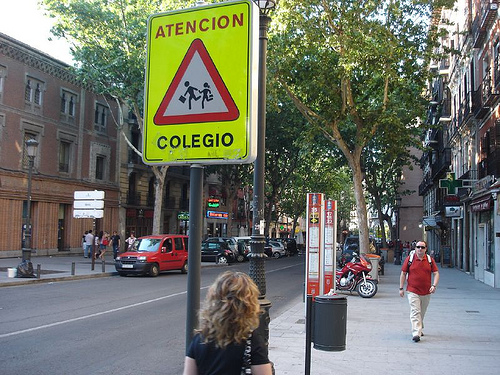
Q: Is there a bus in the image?
A: No, there are no buses.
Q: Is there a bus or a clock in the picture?
A: No, there are no buses or clocks.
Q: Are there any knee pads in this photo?
A: No, there are no knee pads.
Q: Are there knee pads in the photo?
A: No, there are no knee pads.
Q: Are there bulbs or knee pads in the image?
A: No, there are no knee pads or bulbs.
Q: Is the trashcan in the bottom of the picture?
A: Yes, the trashcan is in the bottom of the image.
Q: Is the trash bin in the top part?
A: No, the trash bin is in the bottom of the image.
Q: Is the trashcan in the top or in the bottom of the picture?
A: The trashcan is in the bottom of the image.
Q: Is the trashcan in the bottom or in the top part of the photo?
A: The trashcan is in the bottom of the image.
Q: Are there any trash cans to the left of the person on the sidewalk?
A: Yes, there is a trash can to the left of the person.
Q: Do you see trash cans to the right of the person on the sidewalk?
A: No, the trash can is to the left of the person.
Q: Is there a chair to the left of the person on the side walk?
A: No, there is a trash can to the left of the person.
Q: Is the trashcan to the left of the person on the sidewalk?
A: Yes, the trashcan is to the left of the person.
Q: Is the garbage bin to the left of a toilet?
A: No, the garbage bin is to the left of the person.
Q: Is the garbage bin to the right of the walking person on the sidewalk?
A: No, the garbage bin is to the left of the person.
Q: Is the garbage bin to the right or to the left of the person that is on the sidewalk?
A: The garbage bin is to the left of the person.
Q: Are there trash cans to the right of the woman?
A: Yes, there is a trash can to the right of the woman.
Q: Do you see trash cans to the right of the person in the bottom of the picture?
A: Yes, there is a trash can to the right of the woman.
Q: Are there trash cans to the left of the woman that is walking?
A: No, the trash can is to the right of the woman.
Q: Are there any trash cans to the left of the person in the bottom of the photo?
A: No, the trash can is to the right of the woman.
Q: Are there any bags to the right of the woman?
A: No, there is a trash can to the right of the woman.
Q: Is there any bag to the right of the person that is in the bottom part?
A: No, there is a trash can to the right of the woman.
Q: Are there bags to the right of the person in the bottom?
A: No, there is a trash can to the right of the woman.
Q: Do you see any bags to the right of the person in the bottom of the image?
A: No, there is a trash can to the right of the woman.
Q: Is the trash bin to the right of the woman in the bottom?
A: Yes, the trash bin is to the right of the woman.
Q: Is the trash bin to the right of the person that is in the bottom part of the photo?
A: Yes, the trash bin is to the right of the woman.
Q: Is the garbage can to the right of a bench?
A: No, the garbage can is to the right of the woman.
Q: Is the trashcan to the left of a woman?
A: No, the trashcan is to the right of a woman.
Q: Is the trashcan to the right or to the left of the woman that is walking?
A: The trashcan is to the right of the woman.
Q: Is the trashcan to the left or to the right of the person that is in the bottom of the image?
A: The trashcan is to the right of the woman.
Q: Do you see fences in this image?
A: No, there are no fences.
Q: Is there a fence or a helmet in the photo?
A: No, there are no fences or helmets.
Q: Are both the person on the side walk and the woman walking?
A: Yes, both the person and the woman are walking.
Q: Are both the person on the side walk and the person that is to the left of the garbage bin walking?
A: Yes, both the person and the woman are walking.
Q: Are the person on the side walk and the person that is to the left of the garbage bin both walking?
A: Yes, both the person and the woman are walking.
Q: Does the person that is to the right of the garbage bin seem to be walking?
A: Yes, the person is walking.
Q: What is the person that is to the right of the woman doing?
A: The person is walking.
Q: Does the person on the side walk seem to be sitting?
A: No, the person is walking.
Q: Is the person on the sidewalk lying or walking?
A: The person is walking.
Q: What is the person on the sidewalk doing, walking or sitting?
A: The person is walking.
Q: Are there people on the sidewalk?
A: Yes, there is a person on the sidewalk.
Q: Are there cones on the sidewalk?
A: No, there is a person on the sidewalk.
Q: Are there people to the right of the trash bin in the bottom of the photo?
A: Yes, there is a person to the right of the garbage bin.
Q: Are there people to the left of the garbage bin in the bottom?
A: No, the person is to the right of the garbage bin.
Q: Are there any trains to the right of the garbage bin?
A: No, there is a person to the right of the garbage bin.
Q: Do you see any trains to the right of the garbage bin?
A: No, there is a person to the right of the garbage bin.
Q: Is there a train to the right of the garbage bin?
A: No, there is a person to the right of the garbage bin.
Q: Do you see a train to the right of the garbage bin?
A: No, there is a person to the right of the garbage bin.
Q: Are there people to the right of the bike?
A: Yes, there is a person to the right of the bike.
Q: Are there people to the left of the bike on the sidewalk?
A: No, the person is to the right of the bike.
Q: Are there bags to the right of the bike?
A: No, there is a person to the right of the bike.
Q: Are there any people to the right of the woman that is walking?
A: Yes, there is a person to the right of the woman.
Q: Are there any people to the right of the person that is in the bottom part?
A: Yes, there is a person to the right of the woman.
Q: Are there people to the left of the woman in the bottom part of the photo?
A: No, the person is to the right of the woman.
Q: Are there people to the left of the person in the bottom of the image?
A: No, the person is to the right of the woman.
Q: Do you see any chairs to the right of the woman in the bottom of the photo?
A: No, there is a person to the right of the woman.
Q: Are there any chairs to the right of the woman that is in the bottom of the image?
A: No, there is a person to the right of the woman.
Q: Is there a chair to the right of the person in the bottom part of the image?
A: No, there is a person to the right of the woman.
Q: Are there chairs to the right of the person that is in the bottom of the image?
A: No, there is a person to the right of the woman.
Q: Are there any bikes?
A: Yes, there is a bike.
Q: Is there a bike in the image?
A: Yes, there is a bike.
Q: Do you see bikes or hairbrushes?
A: Yes, there is a bike.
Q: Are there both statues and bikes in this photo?
A: No, there is a bike but no statues.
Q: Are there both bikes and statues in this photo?
A: No, there is a bike but no statues.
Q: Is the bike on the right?
A: Yes, the bike is on the right of the image.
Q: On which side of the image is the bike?
A: The bike is on the right of the image.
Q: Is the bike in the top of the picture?
A: No, the bike is in the bottom of the image.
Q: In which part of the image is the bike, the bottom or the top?
A: The bike is in the bottom of the image.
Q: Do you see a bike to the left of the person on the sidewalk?
A: Yes, there is a bike to the left of the person.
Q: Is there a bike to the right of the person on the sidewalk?
A: No, the bike is to the left of the person.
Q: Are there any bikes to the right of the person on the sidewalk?
A: No, the bike is to the left of the person.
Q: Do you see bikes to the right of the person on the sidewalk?
A: No, the bike is to the left of the person.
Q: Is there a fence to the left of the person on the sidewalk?
A: No, there is a bike to the left of the person.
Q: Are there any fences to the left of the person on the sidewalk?
A: No, there is a bike to the left of the person.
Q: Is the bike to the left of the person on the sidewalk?
A: Yes, the bike is to the left of the person.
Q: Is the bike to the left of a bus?
A: No, the bike is to the left of the person.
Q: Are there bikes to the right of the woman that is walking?
A: Yes, there is a bike to the right of the woman.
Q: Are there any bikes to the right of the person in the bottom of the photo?
A: Yes, there is a bike to the right of the woman.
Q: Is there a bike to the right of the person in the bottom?
A: Yes, there is a bike to the right of the woman.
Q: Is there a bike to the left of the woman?
A: No, the bike is to the right of the woman.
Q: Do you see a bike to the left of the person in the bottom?
A: No, the bike is to the right of the woman.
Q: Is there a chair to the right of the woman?
A: No, there is a bike to the right of the woman.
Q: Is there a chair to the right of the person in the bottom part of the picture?
A: No, there is a bike to the right of the woman.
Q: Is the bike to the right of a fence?
A: No, the bike is to the right of the woman.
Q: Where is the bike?
A: The bike is on the side walk.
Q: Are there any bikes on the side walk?
A: Yes, there is a bike on the side walk.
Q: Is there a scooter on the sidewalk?
A: No, there is a bike on the sidewalk.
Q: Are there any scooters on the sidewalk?
A: No, there is a bike on the sidewalk.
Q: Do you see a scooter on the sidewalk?
A: No, there is a bike on the sidewalk.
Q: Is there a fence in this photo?
A: No, there are no fences.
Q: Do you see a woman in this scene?
A: Yes, there is a woman.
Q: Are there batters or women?
A: Yes, there is a woman.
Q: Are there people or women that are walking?
A: Yes, the woman is walking.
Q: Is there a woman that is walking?
A: Yes, there is a woman that is walking.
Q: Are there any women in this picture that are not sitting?
A: Yes, there is a woman that is walking.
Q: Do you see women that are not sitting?
A: Yes, there is a woman that is walking .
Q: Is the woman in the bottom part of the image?
A: Yes, the woman is in the bottom of the image.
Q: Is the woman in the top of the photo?
A: No, the woman is in the bottom of the image.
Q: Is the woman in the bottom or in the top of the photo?
A: The woman is in the bottom of the image.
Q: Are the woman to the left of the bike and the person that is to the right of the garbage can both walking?
A: Yes, both the woman and the person are walking.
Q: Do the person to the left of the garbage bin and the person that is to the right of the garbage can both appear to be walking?
A: Yes, both the woman and the person are walking.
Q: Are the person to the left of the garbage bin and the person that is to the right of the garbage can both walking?
A: Yes, both the woman and the person are walking.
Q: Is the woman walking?
A: Yes, the woman is walking.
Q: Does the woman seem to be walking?
A: Yes, the woman is walking.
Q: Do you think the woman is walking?
A: Yes, the woman is walking.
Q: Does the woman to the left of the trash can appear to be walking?
A: Yes, the woman is walking.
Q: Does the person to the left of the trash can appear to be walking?
A: Yes, the woman is walking.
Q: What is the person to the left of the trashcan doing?
A: The woman is walking.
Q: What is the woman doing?
A: The woman is walking.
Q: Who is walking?
A: The woman is walking.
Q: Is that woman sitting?
A: No, the woman is walking.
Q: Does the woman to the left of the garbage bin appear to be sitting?
A: No, the woman is walking.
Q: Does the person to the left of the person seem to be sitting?
A: No, the woman is walking.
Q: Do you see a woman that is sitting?
A: No, there is a woman but she is walking.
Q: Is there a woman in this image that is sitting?
A: No, there is a woman but she is walking.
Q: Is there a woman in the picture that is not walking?
A: No, there is a woman but she is walking.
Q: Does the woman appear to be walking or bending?
A: The woman is walking.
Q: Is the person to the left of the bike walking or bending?
A: The woman is walking.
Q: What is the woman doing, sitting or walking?
A: The woman is walking.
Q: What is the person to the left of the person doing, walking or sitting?
A: The woman is walking.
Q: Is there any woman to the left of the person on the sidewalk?
A: Yes, there is a woman to the left of the person.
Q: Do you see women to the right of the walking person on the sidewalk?
A: No, the woman is to the left of the person.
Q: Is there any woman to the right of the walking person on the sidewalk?
A: No, the woman is to the left of the person.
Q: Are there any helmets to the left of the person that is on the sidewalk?
A: No, there is a woman to the left of the person.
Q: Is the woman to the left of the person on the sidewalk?
A: Yes, the woman is to the left of the person.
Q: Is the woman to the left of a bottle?
A: No, the woman is to the left of the person.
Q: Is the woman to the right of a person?
A: No, the woman is to the left of a person.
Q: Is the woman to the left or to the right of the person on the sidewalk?
A: The woman is to the left of the person.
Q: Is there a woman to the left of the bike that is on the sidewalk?
A: Yes, there is a woman to the left of the bike.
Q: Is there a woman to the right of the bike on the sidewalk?
A: No, the woman is to the left of the bike.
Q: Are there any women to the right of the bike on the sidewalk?
A: No, the woman is to the left of the bike.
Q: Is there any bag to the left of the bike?
A: No, there is a woman to the left of the bike.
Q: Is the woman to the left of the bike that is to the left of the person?
A: Yes, the woman is to the left of the bike.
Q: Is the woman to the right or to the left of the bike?
A: The woman is to the left of the bike.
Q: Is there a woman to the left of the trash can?
A: Yes, there is a woman to the left of the trash can.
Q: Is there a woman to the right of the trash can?
A: No, the woman is to the left of the trash can.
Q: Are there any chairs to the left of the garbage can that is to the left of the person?
A: No, there is a woman to the left of the trashcan.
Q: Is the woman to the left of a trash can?
A: Yes, the woman is to the left of a trash can.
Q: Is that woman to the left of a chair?
A: No, the woman is to the left of a trash can.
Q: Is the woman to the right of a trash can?
A: No, the woman is to the left of a trash can.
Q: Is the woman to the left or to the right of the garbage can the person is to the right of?
A: The woman is to the left of the garbage bin.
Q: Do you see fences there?
A: No, there are no fences.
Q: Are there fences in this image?
A: No, there are no fences.